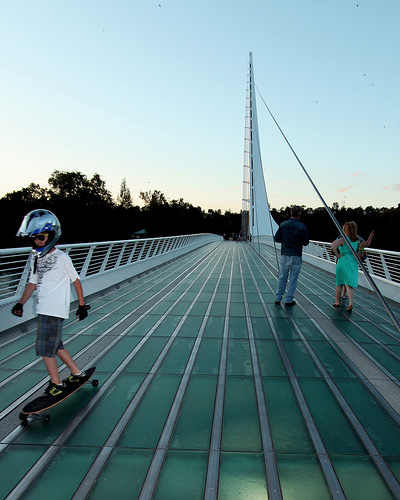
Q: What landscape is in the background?
A: Trees.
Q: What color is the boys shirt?
A: White.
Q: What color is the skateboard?
A: Black.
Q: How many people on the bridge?
A: 3.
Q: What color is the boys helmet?
A: Silver.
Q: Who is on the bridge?
A: 3 people.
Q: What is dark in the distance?
A: Trees.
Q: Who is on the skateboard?
A: A boy.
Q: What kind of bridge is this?
A: Suspension.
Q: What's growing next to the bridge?
A: Trees.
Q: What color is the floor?
A: Green.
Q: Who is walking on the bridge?
A: 3 people.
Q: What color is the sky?
A: Blue.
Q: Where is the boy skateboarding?
A: On a bridge.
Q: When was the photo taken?
A: Sunset.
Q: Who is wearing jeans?
A: The man on the right.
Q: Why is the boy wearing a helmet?
A: For safety.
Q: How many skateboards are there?
A: 1.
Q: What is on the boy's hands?
A: Gloves.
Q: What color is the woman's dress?
A: Greenish-blue.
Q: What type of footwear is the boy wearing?
A: Tennis shoes.